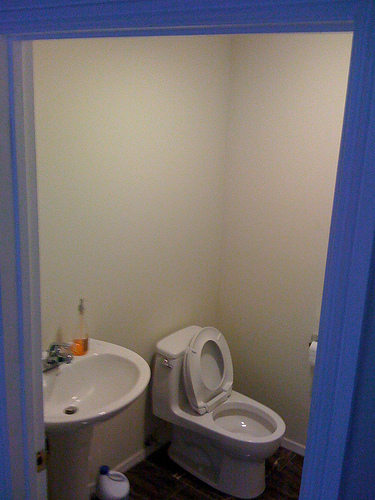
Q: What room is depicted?
A: A bathroom.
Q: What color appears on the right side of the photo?
A: Blue.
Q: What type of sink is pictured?
A: A pedastal sink.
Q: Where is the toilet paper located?
A: To the left of the toilet.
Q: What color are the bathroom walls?
A: Off-white.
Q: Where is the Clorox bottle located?
A: Under the sink on the righthand side.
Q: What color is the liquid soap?
A: Orange.